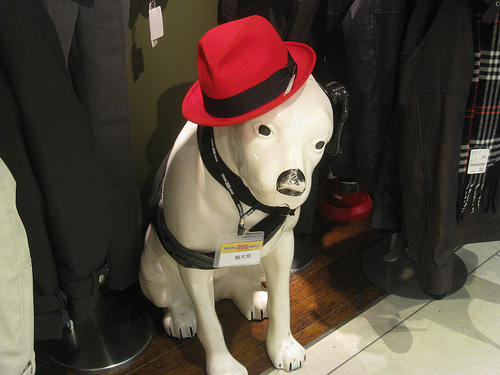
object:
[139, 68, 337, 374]
dog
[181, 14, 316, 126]
hat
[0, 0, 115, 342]
coat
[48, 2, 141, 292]
trouser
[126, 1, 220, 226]
wall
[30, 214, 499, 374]
ground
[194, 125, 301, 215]
neck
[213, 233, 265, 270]
tag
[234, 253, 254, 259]
name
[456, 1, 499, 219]
scarf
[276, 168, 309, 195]
nose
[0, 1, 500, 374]
store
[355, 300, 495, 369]
tile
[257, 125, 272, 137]
eye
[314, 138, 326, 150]
eye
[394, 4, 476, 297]
jacket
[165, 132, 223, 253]
shadow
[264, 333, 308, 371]
paw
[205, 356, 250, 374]
paw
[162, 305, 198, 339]
paw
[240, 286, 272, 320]
paw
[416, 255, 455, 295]
cuff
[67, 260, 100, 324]
cuff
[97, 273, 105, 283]
link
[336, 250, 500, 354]
shadow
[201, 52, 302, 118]
ribbon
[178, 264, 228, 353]
leg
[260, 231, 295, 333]
leg